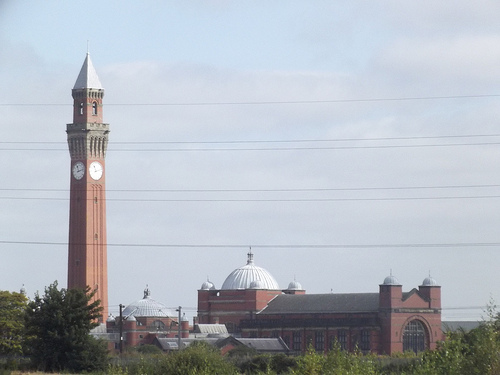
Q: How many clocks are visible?
A: 2.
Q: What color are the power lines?
A: Black.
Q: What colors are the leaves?
A: Green.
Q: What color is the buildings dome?
A: White.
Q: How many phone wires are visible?
A: 6.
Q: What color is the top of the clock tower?
A: Gray.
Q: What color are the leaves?
A: Green.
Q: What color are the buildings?
A: Red brick.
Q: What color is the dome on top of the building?
A: White.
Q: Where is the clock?
A: The clock tower.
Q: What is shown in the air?
A: Several utility lines.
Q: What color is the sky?
A: Blue.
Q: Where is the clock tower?
A: Next to the large brick buildings.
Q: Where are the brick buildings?
A: Next to the tall clock tower.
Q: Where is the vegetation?
A: In front of the buildings and tower.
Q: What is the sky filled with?
A: Clouds.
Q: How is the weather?
A: Cloudy.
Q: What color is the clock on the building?
A: White.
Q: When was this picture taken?
A: Day time.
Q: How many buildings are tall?
A: One.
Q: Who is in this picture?
A: Nobody just buildings.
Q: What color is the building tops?
A: White.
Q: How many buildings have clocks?
A: One.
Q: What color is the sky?
A: Blue.